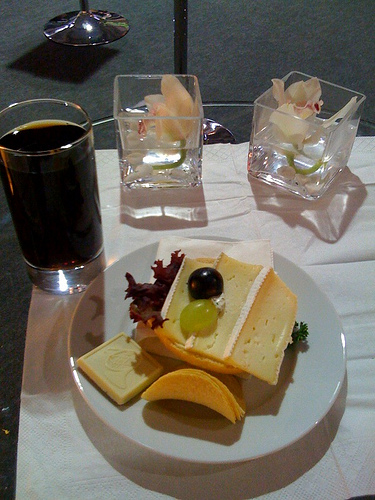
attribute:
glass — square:
[114, 73, 210, 205]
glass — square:
[240, 65, 370, 203]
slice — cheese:
[229, 274, 301, 386]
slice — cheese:
[189, 255, 257, 357]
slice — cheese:
[152, 256, 215, 340]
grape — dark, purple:
[186, 262, 225, 300]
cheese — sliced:
[168, 257, 296, 393]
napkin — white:
[15, 136, 374, 499]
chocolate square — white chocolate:
[66, 328, 165, 416]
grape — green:
[180, 295, 225, 333]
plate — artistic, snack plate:
[296, 274, 335, 331]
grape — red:
[184, 262, 234, 298]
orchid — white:
[269, 76, 356, 175]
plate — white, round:
[65, 234, 347, 463]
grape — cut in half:
[179, 298, 219, 332]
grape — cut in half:
[186, 266, 224, 298]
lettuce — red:
[117, 245, 183, 336]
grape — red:
[189, 264, 229, 296]